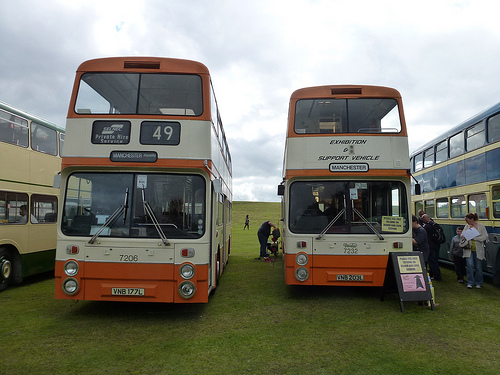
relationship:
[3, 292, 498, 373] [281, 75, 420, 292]
grass in front of bus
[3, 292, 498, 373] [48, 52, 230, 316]
grass in front of bus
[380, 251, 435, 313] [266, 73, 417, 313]
billboard on front of bus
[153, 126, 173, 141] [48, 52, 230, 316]
number on bus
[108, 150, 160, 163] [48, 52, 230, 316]
sign on bus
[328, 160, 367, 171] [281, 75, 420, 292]
sign on bus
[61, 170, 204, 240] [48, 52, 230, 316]
window of bus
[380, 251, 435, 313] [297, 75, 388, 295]
billboard in front of bus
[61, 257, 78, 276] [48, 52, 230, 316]
lights on bus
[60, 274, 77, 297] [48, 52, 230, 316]
lights on bus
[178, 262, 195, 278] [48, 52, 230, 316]
lights on bus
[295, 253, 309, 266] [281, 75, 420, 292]
headlight on bus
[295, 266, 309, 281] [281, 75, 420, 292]
headlight on bus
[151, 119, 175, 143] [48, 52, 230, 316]
number on bus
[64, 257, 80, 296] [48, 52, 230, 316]
headlights on bus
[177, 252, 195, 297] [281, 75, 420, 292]
headlights on bus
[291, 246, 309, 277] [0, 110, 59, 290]
headlights on bus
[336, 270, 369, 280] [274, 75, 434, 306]
license plate on bus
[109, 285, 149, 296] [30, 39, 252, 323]
license plate on bus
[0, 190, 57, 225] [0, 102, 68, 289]
windows on bus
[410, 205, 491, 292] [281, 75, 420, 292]
people standing beside bus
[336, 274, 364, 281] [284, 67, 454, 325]
license plate on bus